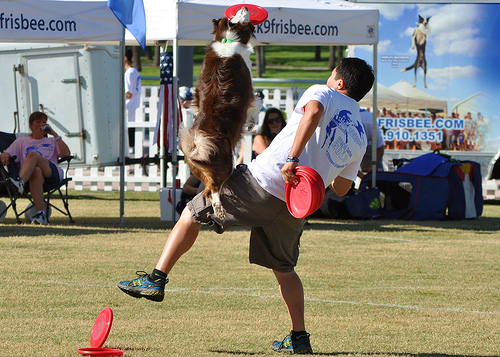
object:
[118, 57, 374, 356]
man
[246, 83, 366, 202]
shirt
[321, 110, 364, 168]
graphic print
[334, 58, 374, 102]
hair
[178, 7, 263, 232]
dog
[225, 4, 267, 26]
frisbee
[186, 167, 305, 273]
shorts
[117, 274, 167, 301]
sneakers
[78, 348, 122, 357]
frisbee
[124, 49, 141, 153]
man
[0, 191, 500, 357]
background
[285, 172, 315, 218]
frisbees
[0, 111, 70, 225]
woman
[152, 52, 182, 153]
flag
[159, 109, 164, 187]
pole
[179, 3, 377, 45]
banner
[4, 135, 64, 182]
shirt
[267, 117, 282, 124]
sunglasses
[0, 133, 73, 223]
chair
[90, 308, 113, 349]
frisbees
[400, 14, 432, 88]
dog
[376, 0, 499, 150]
sign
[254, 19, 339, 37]
letters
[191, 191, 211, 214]
part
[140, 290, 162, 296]
part